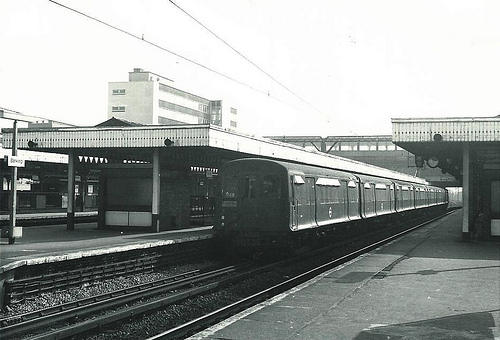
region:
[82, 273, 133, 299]
gravel between the tracks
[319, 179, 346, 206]
windows on a train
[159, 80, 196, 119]
windows in a building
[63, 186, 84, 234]
a pole in the ground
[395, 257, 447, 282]
a shadow on the ground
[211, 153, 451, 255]
long metal train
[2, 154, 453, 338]
train stopped on train tracks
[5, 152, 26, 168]
rectangular white sign with black writing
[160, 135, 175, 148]
black circular object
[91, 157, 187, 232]
small building at train station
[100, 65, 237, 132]
large white building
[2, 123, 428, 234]
white aluminum roof on supports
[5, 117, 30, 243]
sign on a pole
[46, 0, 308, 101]
two power lines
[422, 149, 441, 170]
round black framed light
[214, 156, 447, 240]
train at a train station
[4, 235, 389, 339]
train tracks at the station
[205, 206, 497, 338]
train platform on the right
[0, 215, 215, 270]
train platform to the left of the train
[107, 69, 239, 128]
large white building in the distance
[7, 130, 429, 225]
covered area on the left platform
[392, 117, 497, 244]
covered area on the right platform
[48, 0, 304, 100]
electrical cables over the train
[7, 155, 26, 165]
white station sign on pole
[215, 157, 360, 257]
the front car of the train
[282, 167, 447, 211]
windows on the train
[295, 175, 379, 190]
awning over the windows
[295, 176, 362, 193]
the awnings are white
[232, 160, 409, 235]
the train is dark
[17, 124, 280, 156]
roof over the depot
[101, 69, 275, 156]
high rise behind depot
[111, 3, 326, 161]
wires above the roof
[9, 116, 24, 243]
sign on the pole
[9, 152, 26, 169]
the sign is white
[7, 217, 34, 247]
box on the pole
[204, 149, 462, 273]
a train on track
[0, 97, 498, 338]
a train station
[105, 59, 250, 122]
a building in far left back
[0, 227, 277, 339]
tracks on the ground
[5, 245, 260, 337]
gravel on the tracks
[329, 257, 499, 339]
a casting on the ground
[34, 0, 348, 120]
powerlines above the train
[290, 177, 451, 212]
windows on the train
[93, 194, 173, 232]
a bench for seating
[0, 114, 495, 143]
the roof of train station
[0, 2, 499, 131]
light of daytime sky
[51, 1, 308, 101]
two lines suspended in the air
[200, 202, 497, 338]
surface of train platform